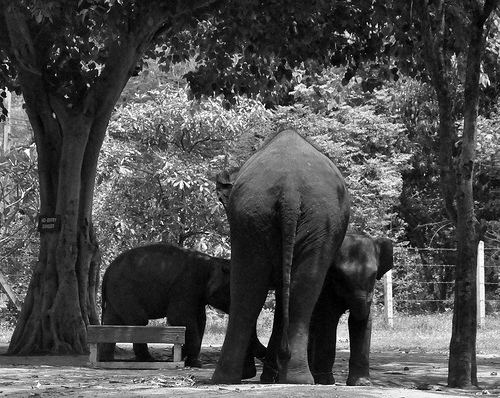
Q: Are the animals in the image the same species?
A: Yes, all the animals are elephants.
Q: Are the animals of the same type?
A: Yes, all the animals are elephants.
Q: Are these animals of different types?
A: No, all the animals are elephants.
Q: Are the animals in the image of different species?
A: No, all the animals are elephants.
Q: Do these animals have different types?
A: No, all the animals are elephants.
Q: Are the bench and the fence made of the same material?
A: No, the bench is made of wood and the fence is made of metal.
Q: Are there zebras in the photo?
A: No, there are no zebras.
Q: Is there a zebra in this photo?
A: No, there are no zebras.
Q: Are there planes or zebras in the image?
A: No, there are no zebras or planes.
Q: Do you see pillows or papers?
A: No, there are no pillows or papers.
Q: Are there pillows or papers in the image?
A: No, there are no pillows or papers.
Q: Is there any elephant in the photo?
A: Yes, there is an elephant.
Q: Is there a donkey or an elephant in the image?
A: Yes, there is an elephant.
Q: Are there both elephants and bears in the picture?
A: No, there is an elephant but no bears.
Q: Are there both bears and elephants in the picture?
A: No, there is an elephant but no bears.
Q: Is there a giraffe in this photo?
A: No, there are no giraffes.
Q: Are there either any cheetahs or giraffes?
A: No, there are no giraffes or cheetahs.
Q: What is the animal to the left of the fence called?
A: The animal is an elephant.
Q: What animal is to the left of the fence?
A: The animal is an elephant.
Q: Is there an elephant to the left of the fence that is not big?
A: Yes, there is an elephant to the left of the fence.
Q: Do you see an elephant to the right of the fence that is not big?
A: No, the elephant is to the left of the fence.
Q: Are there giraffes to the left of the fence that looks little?
A: No, there is an elephant to the left of the fence.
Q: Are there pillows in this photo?
A: No, there are no pillows.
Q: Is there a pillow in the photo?
A: No, there are no pillows.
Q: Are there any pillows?
A: No, there are no pillows.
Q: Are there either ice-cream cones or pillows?
A: No, there are no pillows or ice-cream cones.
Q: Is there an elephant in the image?
A: Yes, there is an elephant.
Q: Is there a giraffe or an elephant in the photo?
A: Yes, there is an elephant.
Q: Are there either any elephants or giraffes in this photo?
A: Yes, there is an elephant.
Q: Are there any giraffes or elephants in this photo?
A: Yes, there is an elephant.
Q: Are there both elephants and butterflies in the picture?
A: No, there is an elephant but no butterflies.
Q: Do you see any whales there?
A: No, there are no whales.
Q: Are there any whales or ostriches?
A: No, there are no whales or ostriches.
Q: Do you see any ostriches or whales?
A: No, there are no whales or ostriches.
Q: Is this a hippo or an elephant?
A: This is an elephant.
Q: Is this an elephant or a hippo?
A: This is an elephant.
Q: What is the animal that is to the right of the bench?
A: The animal is an elephant.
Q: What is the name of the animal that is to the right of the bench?
A: The animal is an elephant.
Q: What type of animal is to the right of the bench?
A: The animal is an elephant.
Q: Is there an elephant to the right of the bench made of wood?
A: Yes, there is an elephant to the right of the bench.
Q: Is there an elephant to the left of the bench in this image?
A: No, the elephant is to the right of the bench.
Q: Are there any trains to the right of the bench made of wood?
A: No, there is an elephant to the right of the bench.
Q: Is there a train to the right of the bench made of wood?
A: No, there is an elephant to the right of the bench.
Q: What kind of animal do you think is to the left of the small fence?
A: The animal is an elephant.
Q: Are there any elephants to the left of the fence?
A: Yes, there is an elephant to the left of the fence.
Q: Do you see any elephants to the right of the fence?
A: No, the elephant is to the left of the fence.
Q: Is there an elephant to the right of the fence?
A: No, the elephant is to the left of the fence.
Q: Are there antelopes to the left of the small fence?
A: No, there is an elephant to the left of the fence.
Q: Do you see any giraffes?
A: No, there are no giraffes.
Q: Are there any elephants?
A: Yes, there is an elephant.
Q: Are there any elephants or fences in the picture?
A: Yes, there is an elephant.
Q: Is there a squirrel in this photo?
A: No, there are no squirrels.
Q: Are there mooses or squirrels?
A: No, there are no squirrels or mooses.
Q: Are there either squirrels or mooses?
A: No, there are no squirrels or mooses.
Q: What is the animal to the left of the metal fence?
A: The animal is an elephant.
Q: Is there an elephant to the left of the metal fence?
A: Yes, there is an elephant to the left of the fence.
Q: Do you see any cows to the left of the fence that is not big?
A: No, there is an elephant to the left of the fence.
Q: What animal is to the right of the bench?
A: The animal is an elephant.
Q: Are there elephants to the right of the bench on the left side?
A: Yes, there is an elephant to the right of the bench.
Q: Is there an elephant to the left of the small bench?
A: No, the elephant is to the right of the bench.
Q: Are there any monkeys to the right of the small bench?
A: No, there is an elephant to the right of the bench.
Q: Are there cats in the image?
A: No, there are no cats.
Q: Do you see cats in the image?
A: No, there are no cats.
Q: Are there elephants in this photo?
A: Yes, there is an elephant.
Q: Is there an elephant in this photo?
A: Yes, there is an elephant.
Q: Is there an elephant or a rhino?
A: Yes, there is an elephant.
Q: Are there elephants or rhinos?
A: Yes, there is an elephant.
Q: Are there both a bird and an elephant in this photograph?
A: No, there is an elephant but no birds.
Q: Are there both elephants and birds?
A: No, there is an elephant but no birds.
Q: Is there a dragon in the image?
A: No, there are no dragons.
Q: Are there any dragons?
A: No, there are no dragons.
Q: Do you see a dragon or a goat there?
A: No, there are no dragons or goats.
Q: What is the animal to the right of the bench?
A: The animal is an elephant.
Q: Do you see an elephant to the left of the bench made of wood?
A: No, the elephant is to the right of the bench.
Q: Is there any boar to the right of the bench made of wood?
A: No, there is an elephant to the right of the bench.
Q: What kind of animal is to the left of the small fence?
A: The animal is an elephant.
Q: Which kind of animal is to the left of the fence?
A: The animal is an elephant.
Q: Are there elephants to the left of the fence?
A: Yes, there is an elephant to the left of the fence.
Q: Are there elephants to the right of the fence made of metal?
A: No, the elephant is to the left of the fence.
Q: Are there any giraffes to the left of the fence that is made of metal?
A: No, there is an elephant to the left of the fence.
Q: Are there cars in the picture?
A: No, there are no cars.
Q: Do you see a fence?
A: Yes, there is a fence.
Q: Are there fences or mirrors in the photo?
A: Yes, there is a fence.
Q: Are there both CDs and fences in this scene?
A: No, there is a fence but no cds.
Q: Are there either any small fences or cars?
A: Yes, there is a small fence.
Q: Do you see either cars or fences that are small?
A: Yes, the fence is small.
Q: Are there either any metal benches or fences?
A: Yes, there is a metal fence.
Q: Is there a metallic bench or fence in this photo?
A: Yes, there is a metal fence.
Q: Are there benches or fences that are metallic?
A: Yes, the fence is metallic.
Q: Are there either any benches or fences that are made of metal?
A: Yes, the fence is made of metal.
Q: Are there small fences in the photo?
A: Yes, there is a small fence.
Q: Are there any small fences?
A: Yes, there is a small fence.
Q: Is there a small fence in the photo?
A: Yes, there is a small fence.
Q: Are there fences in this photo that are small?
A: Yes, there is a fence that is small.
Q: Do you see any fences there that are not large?
A: Yes, there is a small fence.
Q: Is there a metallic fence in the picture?
A: Yes, there is a metal fence.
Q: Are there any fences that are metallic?
A: Yes, there is a fence that is metallic.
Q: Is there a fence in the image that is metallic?
A: Yes, there is a fence that is metallic.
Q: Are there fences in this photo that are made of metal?
A: Yes, there is a fence that is made of metal.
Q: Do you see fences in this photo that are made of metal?
A: Yes, there is a fence that is made of metal.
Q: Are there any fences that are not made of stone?
A: Yes, there is a fence that is made of metal.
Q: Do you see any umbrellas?
A: No, there are no umbrellas.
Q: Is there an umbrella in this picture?
A: No, there are no umbrellas.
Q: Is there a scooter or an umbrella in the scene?
A: No, there are no umbrellas or scooters.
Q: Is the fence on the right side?
A: Yes, the fence is on the right of the image.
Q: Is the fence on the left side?
A: No, the fence is on the right of the image.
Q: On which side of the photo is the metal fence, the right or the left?
A: The fence is on the right of the image.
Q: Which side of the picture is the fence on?
A: The fence is on the right of the image.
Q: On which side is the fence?
A: The fence is on the right of the image.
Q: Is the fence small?
A: Yes, the fence is small.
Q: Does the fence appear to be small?
A: Yes, the fence is small.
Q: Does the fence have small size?
A: Yes, the fence is small.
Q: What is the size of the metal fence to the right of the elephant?
A: The fence is small.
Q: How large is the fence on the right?
A: The fence is small.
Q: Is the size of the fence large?
A: No, the fence is small.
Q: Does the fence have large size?
A: No, the fence is small.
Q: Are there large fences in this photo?
A: No, there is a fence but it is small.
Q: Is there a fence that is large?
A: No, there is a fence but it is small.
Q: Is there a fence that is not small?
A: No, there is a fence but it is small.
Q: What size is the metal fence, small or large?
A: The fence is small.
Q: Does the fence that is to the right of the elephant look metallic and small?
A: Yes, the fence is metallic and small.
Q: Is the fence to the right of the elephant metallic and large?
A: No, the fence is metallic but small.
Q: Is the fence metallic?
A: Yes, the fence is metallic.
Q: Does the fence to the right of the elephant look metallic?
A: Yes, the fence is metallic.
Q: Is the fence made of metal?
A: Yes, the fence is made of metal.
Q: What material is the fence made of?
A: The fence is made of metal.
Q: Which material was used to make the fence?
A: The fence is made of metal.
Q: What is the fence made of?
A: The fence is made of metal.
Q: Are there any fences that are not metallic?
A: No, there is a fence but it is metallic.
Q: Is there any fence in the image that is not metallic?
A: No, there is a fence but it is metallic.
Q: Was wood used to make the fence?
A: No, the fence is made of metal.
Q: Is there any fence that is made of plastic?
A: No, there is a fence but it is made of metal.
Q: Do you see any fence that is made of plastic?
A: No, there is a fence but it is made of metal.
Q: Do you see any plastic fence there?
A: No, there is a fence but it is made of metal.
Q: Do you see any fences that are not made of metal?
A: No, there is a fence but it is made of metal.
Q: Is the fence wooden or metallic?
A: The fence is metallic.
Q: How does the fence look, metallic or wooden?
A: The fence is metallic.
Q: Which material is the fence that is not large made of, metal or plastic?
A: The fence is made of metal.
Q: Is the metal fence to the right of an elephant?
A: Yes, the fence is to the right of an elephant.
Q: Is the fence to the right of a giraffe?
A: No, the fence is to the right of an elephant.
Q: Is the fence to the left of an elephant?
A: No, the fence is to the right of an elephant.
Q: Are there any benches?
A: Yes, there is a bench.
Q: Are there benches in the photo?
A: Yes, there is a bench.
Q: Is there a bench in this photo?
A: Yes, there is a bench.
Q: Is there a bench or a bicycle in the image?
A: Yes, there is a bench.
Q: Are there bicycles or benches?
A: Yes, there is a bench.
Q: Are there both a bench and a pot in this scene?
A: No, there is a bench but no pots.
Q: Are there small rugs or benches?
A: Yes, there is a small bench.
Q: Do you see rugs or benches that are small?
A: Yes, the bench is small.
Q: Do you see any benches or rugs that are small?
A: Yes, the bench is small.